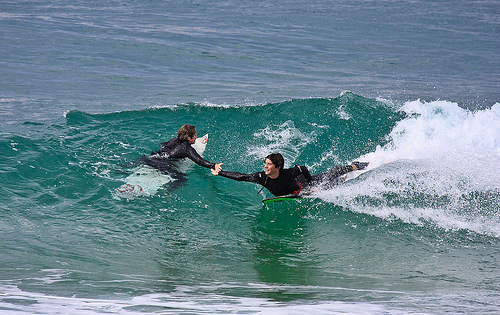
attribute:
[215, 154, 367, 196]
surfer — smiling, prone, surfing, swimming, white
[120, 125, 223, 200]
surfer — prone, surfing, swimming, white, girl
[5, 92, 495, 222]
wave — crashed, rolling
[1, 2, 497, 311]
water — bllue, wet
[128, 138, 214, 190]
wet suit — black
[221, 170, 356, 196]
wet suit — black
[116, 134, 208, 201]
board — white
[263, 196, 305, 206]
board — green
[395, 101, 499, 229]
water — white, foamed, splashing, bubbly, rough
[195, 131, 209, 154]
nose — up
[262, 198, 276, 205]
nose — up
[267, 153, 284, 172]
cap — black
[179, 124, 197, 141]
hair — long